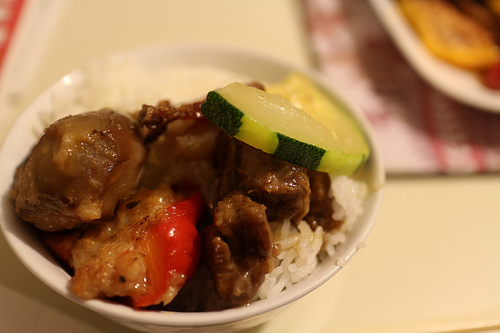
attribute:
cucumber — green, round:
[210, 86, 345, 161]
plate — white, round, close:
[366, 170, 390, 229]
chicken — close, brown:
[92, 204, 192, 308]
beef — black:
[37, 120, 147, 194]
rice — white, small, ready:
[294, 227, 335, 279]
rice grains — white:
[254, 225, 320, 289]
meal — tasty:
[18, 68, 358, 315]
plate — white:
[2, 32, 394, 332]